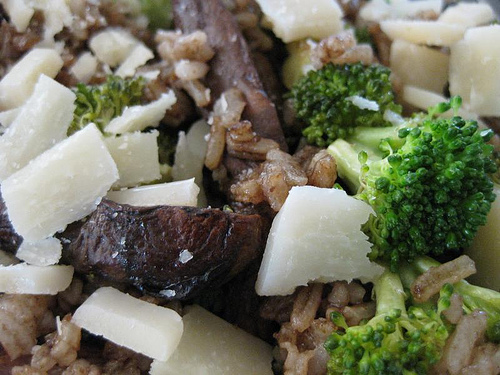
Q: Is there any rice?
A: Yes, there is rice.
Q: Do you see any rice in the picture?
A: Yes, there is rice.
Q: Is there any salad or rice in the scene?
A: Yes, there is rice.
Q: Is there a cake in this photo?
A: No, there are no cakes.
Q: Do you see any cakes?
A: No, there are no cakes.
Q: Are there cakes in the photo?
A: No, there are no cakes.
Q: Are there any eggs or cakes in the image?
A: No, there are no cakes or eggs.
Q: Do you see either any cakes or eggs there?
A: No, there are no cakes or eggs.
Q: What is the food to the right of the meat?
A: The food is rice.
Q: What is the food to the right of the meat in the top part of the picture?
A: The food is rice.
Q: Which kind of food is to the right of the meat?
A: The food is rice.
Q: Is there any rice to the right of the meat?
A: Yes, there is rice to the right of the meat.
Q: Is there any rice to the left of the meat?
A: No, the rice is to the right of the meat.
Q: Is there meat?
A: Yes, there is meat.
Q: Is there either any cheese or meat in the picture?
A: Yes, there is meat.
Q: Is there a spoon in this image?
A: No, there are no spoons.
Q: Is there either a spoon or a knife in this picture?
A: No, there are no spoons or knives.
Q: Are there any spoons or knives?
A: No, there are no spoons or knives.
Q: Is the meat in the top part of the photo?
A: Yes, the meat is in the top of the image.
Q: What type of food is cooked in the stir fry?
A: The food is meat.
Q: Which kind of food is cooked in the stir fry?
A: The food is meat.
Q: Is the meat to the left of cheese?
A: No, the meat is to the left of the rice.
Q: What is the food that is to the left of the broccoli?
A: The food is meat.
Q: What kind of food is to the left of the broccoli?
A: The food is meat.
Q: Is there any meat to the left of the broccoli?
A: Yes, there is meat to the left of the broccoli.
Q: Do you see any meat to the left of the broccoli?
A: Yes, there is meat to the left of the broccoli.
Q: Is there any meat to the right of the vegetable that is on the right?
A: No, the meat is to the left of the broccoli.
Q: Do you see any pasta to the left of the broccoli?
A: No, there is meat to the left of the broccoli.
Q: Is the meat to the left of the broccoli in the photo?
A: Yes, the meat is to the left of the broccoli.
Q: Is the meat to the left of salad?
A: No, the meat is to the left of the broccoli.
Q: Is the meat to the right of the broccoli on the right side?
A: No, the meat is to the left of the broccoli.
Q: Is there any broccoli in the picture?
A: Yes, there is broccoli.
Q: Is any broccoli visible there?
A: Yes, there is broccoli.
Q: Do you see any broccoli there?
A: Yes, there is broccoli.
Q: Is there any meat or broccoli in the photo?
A: Yes, there is broccoli.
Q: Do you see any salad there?
A: No, there is no salad.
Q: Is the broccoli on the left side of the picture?
A: No, the broccoli is on the right of the image.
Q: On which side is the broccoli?
A: The broccoli is on the right of the image.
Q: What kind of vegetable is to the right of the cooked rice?
A: The vegetable is broccoli.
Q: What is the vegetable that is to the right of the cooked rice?
A: The vegetable is broccoli.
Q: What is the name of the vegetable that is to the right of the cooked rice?
A: The vegetable is broccoli.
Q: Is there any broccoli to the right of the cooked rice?
A: Yes, there is broccoli to the right of the rice.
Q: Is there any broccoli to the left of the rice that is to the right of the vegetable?
A: No, the broccoli is to the right of the rice.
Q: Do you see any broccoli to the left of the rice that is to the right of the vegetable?
A: No, the broccoli is to the right of the rice.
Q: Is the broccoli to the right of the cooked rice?
A: Yes, the broccoli is to the right of the rice.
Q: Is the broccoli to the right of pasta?
A: No, the broccoli is to the right of the rice.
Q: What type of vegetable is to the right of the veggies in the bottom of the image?
A: The vegetable is broccoli.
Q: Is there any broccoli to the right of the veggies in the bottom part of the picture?
A: Yes, there is broccoli to the right of the veggies.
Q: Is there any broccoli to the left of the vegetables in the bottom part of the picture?
A: No, the broccoli is to the right of the veggies.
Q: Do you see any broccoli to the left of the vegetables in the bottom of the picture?
A: No, the broccoli is to the right of the veggies.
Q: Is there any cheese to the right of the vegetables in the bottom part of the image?
A: No, there is broccoli to the right of the vegetables.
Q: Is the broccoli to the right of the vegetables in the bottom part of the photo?
A: Yes, the broccoli is to the right of the vegetables.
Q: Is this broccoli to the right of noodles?
A: No, the broccoli is to the right of the vegetables.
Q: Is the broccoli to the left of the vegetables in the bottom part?
A: No, the broccoli is to the right of the vegetables.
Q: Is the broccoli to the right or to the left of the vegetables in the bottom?
A: The broccoli is to the right of the veggies.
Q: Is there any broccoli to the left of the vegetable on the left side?
A: No, the broccoli is to the right of the vegetable.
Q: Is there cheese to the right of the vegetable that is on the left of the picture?
A: No, there is broccoli to the right of the vegetable.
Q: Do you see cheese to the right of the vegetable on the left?
A: No, there is broccoli to the right of the vegetable.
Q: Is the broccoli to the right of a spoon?
A: No, the broccoli is to the right of a vegetable.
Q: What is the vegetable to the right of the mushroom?
A: The vegetable is broccoli.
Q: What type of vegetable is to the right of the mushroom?
A: The vegetable is broccoli.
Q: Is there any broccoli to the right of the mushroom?
A: Yes, there is broccoli to the right of the mushroom.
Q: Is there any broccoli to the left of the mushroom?
A: No, the broccoli is to the right of the mushroom.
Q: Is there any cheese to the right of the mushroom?
A: No, there is broccoli to the right of the mushroom.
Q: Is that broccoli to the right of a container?
A: No, the broccoli is to the right of the mushroom.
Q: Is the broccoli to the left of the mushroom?
A: No, the broccoli is to the right of the mushroom.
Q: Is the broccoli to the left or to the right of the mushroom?
A: The broccoli is to the right of the mushroom.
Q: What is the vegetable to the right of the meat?
A: The vegetable is broccoli.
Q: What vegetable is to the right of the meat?
A: The vegetable is broccoli.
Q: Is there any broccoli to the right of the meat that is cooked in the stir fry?
A: Yes, there is broccoli to the right of the meat.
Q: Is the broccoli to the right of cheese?
A: No, the broccoli is to the right of the meat.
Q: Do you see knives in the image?
A: No, there are no knives.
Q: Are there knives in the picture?
A: No, there are no knives.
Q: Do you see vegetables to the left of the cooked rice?
A: Yes, there is a vegetable to the left of the rice.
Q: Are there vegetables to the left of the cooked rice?
A: Yes, there is a vegetable to the left of the rice.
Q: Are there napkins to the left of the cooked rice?
A: No, there is a vegetable to the left of the rice.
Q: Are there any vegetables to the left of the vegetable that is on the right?
A: Yes, there is a vegetable to the left of the broccoli.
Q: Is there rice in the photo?
A: Yes, there is rice.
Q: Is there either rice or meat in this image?
A: Yes, there is rice.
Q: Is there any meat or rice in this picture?
A: Yes, there is rice.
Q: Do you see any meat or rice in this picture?
A: Yes, there is rice.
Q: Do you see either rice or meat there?
A: Yes, there is rice.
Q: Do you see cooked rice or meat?
A: Yes, there is cooked rice.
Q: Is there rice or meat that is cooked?
A: Yes, the rice is cooked.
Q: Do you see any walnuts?
A: No, there are no walnuts.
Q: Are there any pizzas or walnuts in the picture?
A: No, there are no walnuts or pizzas.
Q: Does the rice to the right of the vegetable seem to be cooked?
A: Yes, the rice is cooked.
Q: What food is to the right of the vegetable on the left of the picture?
A: The food is rice.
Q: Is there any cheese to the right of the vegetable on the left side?
A: No, there is rice to the right of the vegetable.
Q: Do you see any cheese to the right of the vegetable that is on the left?
A: No, there is rice to the right of the vegetable.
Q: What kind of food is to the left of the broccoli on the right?
A: The food is rice.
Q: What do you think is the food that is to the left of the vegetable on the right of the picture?
A: The food is rice.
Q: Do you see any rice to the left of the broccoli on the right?
A: Yes, there is rice to the left of the broccoli.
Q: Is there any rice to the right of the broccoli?
A: No, the rice is to the left of the broccoli.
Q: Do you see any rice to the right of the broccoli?
A: No, the rice is to the left of the broccoli.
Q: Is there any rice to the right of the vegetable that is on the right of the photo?
A: No, the rice is to the left of the broccoli.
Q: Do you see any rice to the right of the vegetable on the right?
A: No, the rice is to the left of the broccoli.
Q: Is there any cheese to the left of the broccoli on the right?
A: No, there is rice to the left of the broccoli.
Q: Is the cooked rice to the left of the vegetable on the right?
A: Yes, the rice is to the left of the broccoli.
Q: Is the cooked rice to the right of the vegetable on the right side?
A: No, the rice is to the left of the broccoli.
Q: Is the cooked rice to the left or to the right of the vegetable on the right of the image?
A: The rice is to the left of the broccoli.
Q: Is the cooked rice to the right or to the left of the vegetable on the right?
A: The rice is to the left of the broccoli.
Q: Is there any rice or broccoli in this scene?
A: Yes, there is rice.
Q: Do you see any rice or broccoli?
A: Yes, there is rice.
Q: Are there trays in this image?
A: No, there are no trays.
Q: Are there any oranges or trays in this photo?
A: No, there are no trays or oranges.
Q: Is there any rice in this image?
A: Yes, there is rice.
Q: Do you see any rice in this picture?
A: Yes, there is rice.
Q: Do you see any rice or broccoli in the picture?
A: Yes, there is rice.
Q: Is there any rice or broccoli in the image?
A: Yes, there is rice.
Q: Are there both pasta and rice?
A: No, there is rice but no pasta.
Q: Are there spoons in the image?
A: No, there are no spoons.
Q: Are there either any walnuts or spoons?
A: No, there are no spoons or walnuts.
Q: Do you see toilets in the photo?
A: No, there are no toilets.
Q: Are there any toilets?
A: No, there are no toilets.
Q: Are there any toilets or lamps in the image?
A: No, there are no toilets or lamps.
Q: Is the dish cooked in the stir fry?
A: Yes, the dish is cooked in the stir fry.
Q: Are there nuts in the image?
A: No, there are no nuts.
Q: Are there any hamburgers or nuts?
A: No, there are no nuts or hamburgers.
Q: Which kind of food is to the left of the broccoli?
A: The food is a mushroom.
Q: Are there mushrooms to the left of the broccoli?
A: Yes, there is a mushroom to the left of the broccoli.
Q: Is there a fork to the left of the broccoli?
A: No, there is a mushroom to the left of the broccoli.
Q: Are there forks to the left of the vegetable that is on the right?
A: No, there is a mushroom to the left of the broccoli.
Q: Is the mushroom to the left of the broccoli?
A: Yes, the mushroom is to the left of the broccoli.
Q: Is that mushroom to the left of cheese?
A: No, the mushroom is to the left of the broccoli.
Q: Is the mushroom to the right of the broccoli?
A: No, the mushroom is to the left of the broccoli.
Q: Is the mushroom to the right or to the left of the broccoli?
A: The mushroom is to the left of the broccoli.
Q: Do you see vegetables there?
A: Yes, there are vegetables.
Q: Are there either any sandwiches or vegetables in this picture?
A: Yes, there are vegetables.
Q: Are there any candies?
A: No, there are no candies.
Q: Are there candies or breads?
A: No, there are no candies or breads.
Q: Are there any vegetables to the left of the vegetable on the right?
A: Yes, there are vegetables to the left of the broccoli.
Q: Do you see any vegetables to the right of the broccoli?
A: No, the vegetables are to the left of the broccoli.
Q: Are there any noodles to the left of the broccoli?
A: No, there are vegetables to the left of the broccoli.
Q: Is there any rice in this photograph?
A: Yes, there is rice.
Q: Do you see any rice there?
A: Yes, there is rice.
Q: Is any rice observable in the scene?
A: Yes, there is rice.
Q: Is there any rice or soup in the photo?
A: Yes, there is rice.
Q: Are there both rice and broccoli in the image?
A: Yes, there are both rice and broccoli.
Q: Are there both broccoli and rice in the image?
A: Yes, there are both rice and broccoli.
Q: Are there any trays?
A: No, there are no trays.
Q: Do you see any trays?
A: No, there are no trays.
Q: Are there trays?
A: No, there are no trays.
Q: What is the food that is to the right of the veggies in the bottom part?
A: The food is rice.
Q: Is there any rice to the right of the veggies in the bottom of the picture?
A: Yes, there is rice to the right of the veggies.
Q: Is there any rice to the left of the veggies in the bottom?
A: No, the rice is to the right of the veggies.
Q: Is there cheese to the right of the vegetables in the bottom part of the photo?
A: No, there is rice to the right of the vegetables.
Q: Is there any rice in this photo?
A: Yes, there is rice.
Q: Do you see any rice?
A: Yes, there is rice.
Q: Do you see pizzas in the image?
A: No, there are no pizzas.